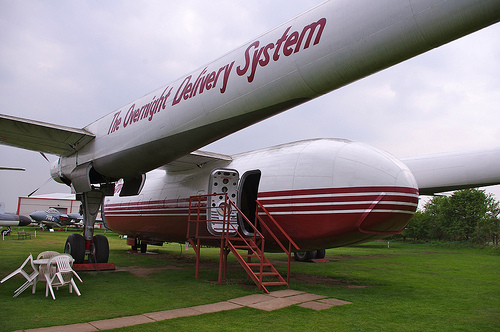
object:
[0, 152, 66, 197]
propeller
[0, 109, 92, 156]
wing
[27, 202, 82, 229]
blue plane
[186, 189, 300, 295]
ladder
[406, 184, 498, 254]
trees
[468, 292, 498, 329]
grass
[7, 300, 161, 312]
grass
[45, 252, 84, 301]
chair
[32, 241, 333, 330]
path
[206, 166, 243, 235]
airplane door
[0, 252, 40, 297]
chairs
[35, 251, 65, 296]
chairs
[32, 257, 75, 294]
table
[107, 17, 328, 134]
advertisement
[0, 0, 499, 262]
airplane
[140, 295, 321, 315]
walkway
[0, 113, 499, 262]
airplane